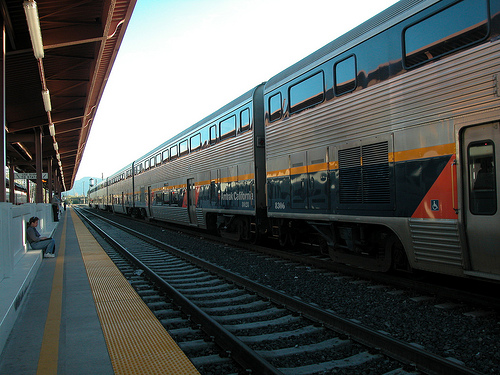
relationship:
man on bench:
[21, 215, 56, 258] [22, 219, 42, 248]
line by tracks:
[35, 206, 68, 375] [71, 202, 489, 373]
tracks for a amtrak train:
[71, 202, 489, 373] [87, 0, 500, 283]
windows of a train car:
[150, 132, 202, 154] [181, 94, 394, 239]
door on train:
[457, 123, 497, 274] [69, 32, 499, 285]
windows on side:
[134, 132, 201, 176] [85, 1, 499, 287]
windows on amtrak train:
[134, 132, 201, 176] [87, 0, 500, 283]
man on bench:
[27, 216, 56, 258] [0, 200, 65, 357]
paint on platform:
[35, 206, 206, 375] [4, 190, 85, 370]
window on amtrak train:
[323, 58, 370, 102] [87, 0, 500, 283]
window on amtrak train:
[286, 77, 331, 101] [87, 0, 500, 283]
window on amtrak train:
[265, 87, 285, 116] [87, 0, 500, 283]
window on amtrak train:
[240, 97, 257, 124] [87, 0, 500, 283]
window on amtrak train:
[215, 110, 246, 137] [87, 0, 500, 283]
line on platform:
[47, 245, 67, 367] [14, 36, 384, 352]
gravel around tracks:
[132, 234, 442, 370] [103, 219, 267, 340]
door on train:
[457, 119, 500, 276] [128, 6, 498, 260]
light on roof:
[17, 0, 46, 61] [2, 2, 113, 187]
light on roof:
[38, 88, 55, 112] [2, 2, 113, 187]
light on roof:
[47, 123, 58, 135] [2, 2, 113, 187]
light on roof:
[57, 153, 61, 164] [2, 2, 113, 187]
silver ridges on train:
[368, 67, 443, 104] [83, 0, 498, 312]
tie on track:
[152, 290, 258, 310] [71, 205, 468, 375]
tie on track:
[159, 304, 286, 326] [71, 205, 468, 375]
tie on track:
[170, 312, 305, 337] [71, 205, 468, 375]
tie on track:
[176, 322, 322, 349] [71, 205, 468, 375]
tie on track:
[189, 335, 349, 367] [71, 205, 468, 375]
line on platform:
[35, 206, 68, 375] [29, 214, 187, 366]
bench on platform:
[1, 191, 59, 340] [4, 202, 109, 374]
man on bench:
[27, 216, 56, 258] [0, 201, 42, 346]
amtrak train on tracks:
[87, 0, 500, 283] [105, 198, 498, 318]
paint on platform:
[56, 192, 206, 374] [1, 194, 68, 347]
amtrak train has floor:
[87, 0, 500, 283] [87, 118, 498, 302]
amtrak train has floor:
[87, 0, 500, 283] [86, 2, 498, 194]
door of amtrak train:
[457, 119, 500, 276] [87, 0, 500, 283]